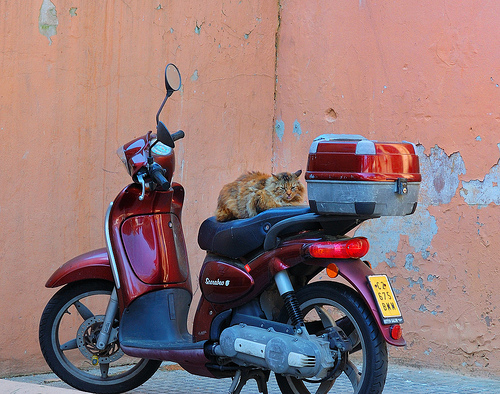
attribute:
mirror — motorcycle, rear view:
[160, 55, 188, 103]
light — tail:
[300, 221, 384, 270]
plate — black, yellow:
[367, 274, 403, 326]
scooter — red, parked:
[23, 116, 458, 389]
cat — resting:
[218, 165, 301, 223]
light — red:
[312, 239, 372, 260]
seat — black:
[202, 210, 311, 259]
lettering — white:
[199, 279, 237, 289]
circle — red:
[387, 322, 403, 341]